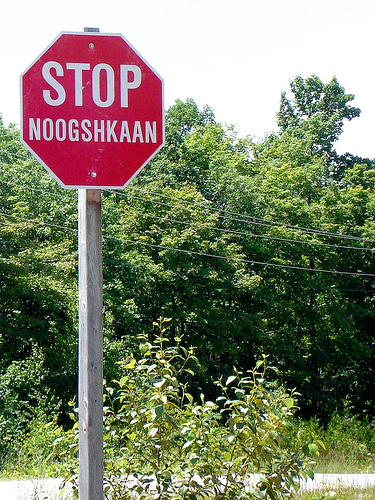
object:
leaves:
[225, 373, 237, 387]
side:
[0, 380, 374, 492]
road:
[4, 455, 373, 498]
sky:
[0, 1, 373, 163]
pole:
[76, 189, 103, 498]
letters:
[142, 118, 158, 147]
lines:
[0, 212, 374, 275]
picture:
[0, 0, 373, 498]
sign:
[16, 24, 164, 191]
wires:
[0, 179, 373, 251]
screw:
[85, 41, 100, 53]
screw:
[88, 168, 100, 179]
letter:
[103, 117, 126, 145]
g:
[68, 118, 79, 147]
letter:
[65, 57, 92, 114]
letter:
[117, 61, 144, 109]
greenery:
[28, 323, 328, 498]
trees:
[274, 70, 359, 183]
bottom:
[63, 156, 128, 188]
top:
[63, 38, 121, 63]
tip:
[82, 27, 100, 34]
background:
[0, 0, 374, 498]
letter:
[92, 117, 106, 144]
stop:
[39, 58, 147, 112]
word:
[26, 115, 157, 145]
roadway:
[4, 469, 374, 493]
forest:
[0, 67, 375, 435]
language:
[24, 61, 158, 140]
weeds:
[0, 410, 364, 500]